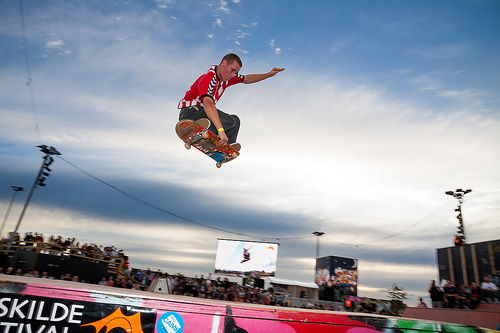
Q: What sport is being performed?
A: Skateboarding.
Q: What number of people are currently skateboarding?
A: One.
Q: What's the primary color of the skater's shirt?
A: Red.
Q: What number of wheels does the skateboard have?
A: Four.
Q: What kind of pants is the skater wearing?
A: Jeans.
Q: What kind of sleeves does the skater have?
A: Short sleeves.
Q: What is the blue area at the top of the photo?
A: The sky.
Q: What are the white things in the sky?
A: Clouds.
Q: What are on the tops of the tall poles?
A: Lights.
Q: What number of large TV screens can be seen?
A: One.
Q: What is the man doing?
A: Jumping on a skateboard.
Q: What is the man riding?
A: A skateboard.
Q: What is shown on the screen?
A: The man on the skateboard.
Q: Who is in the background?
A: Spectators.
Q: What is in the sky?
A: Clouds.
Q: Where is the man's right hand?
A: In the air.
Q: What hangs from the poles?
A: Wires.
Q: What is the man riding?
A: A skateboard.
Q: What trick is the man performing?
A: A jump.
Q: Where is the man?
A: On a skateboard.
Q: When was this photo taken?
A: When the skateboarder was in midair.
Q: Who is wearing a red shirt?
A: The man on the skateboard.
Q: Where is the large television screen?
A: Behind the man in the background.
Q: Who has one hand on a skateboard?
A: The man with the red shirt.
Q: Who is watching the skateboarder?
A: The people in the stands in the background.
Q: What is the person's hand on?
A: Skateboard.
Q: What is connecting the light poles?
A: Wire.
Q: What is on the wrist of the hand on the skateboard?
A: Yellow band.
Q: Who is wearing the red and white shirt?
A: Skateboarder.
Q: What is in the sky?
A: Clouds.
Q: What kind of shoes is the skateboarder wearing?
A: Tennis shoes.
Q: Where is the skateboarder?
A: In the air.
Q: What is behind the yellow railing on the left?
A: Fans.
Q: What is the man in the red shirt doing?
A: Skateboarding.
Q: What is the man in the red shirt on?
A: A skateboard.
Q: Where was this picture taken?
A: At a skateboard event.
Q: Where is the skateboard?
A: In the air.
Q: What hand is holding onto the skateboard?
A: The right hand.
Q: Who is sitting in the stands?
A: A crowd.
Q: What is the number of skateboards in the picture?
A: One.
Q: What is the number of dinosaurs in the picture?
A: Zero.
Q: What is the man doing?
A: Skateboarding.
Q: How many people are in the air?
A: 1.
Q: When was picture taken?
A: Daytime.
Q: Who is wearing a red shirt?
A: Man.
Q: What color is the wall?
A: Multi-colored.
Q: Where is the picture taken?
A: Skatepark.